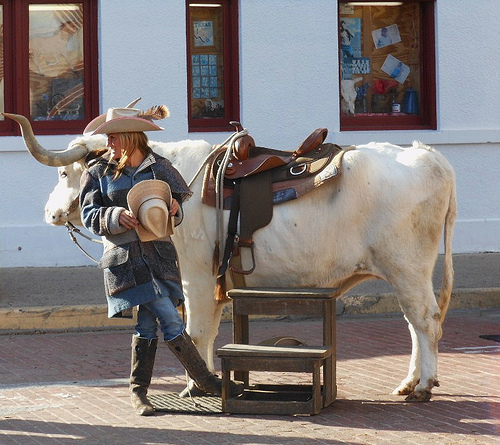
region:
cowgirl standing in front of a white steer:
[1, 97, 454, 414]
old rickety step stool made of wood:
[217, 286, 340, 415]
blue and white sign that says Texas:
[193, 20, 215, 48]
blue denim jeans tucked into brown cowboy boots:
[128, 295, 243, 415]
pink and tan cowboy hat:
[82, 105, 169, 137]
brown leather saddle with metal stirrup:
[201, 119, 353, 302]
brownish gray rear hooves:
[393, 382, 434, 402]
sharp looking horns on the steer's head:
[1, 96, 143, 226]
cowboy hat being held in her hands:
[118, 178, 178, 242]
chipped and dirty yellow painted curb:
[0, 286, 499, 333]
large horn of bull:
[7, 98, 89, 190]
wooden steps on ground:
[216, 266, 346, 429]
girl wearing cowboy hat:
[83, 92, 177, 191]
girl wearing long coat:
[86, 126, 177, 312]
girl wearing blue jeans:
[95, 107, 195, 342]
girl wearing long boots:
[105, 117, 225, 421]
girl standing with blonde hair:
[66, 99, 176, 179]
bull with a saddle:
[188, 114, 427, 271]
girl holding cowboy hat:
[102, 169, 212, 269]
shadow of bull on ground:
[368, 384, 498, 436]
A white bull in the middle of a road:
[6, 92, 467, 418]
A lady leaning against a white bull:
[67, 97, 244, 420]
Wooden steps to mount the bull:
[204, 277, 355, 425]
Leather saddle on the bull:
[201, 118, 351, 275]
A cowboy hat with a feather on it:
[75, 91, 170, 138]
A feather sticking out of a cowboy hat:
[137, 103, 175, 119]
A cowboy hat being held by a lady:
[125, 175, 179, 246]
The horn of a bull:
[2, 101, 89, 171]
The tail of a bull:
[441, 187, 457, 351]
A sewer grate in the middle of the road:
[118, 367, 266, 427]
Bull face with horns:
[3, 85, 107, 231]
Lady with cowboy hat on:
[81, 92, 179, 174]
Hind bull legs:
[369, 273, 453, 412]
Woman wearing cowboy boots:
[97, 124, 212, 433]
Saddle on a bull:
[56, 91, 423, 238]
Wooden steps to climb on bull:
[189, 221, 337, 415]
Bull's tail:
[432, 183, 465, 353]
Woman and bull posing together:
[36, 66, 478, 378]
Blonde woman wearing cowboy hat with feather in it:
[62, 95, 191, 193]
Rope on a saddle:
[193, 77, 253, 218]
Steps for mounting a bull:
[211, 282, 342, 416]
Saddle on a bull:
[209, 115, 347, 290]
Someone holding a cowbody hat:
[73, 100, 222, 421]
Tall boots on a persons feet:
[92, 324, 222, 421]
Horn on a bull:
[3, 106, 87, 173]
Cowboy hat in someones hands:
[112, 178, 177, 245]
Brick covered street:
[34, 401, 126, 437]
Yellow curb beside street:
[12, 299, 90, 332]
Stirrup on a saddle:
[217, 230, 269, 278]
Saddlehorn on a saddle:
[224, 115, 246, 139]